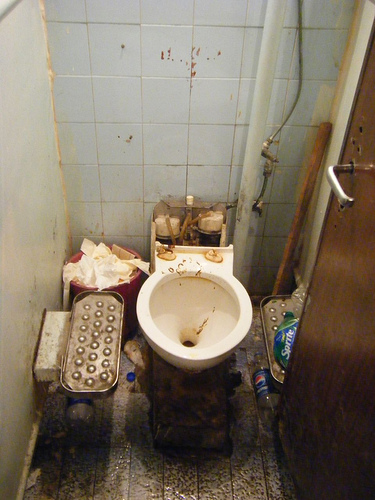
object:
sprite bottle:
[272, 310, 299, 371]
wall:
[42, 0, 358, 299]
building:
[0, 0, 374, 498]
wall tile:
[87, 23, 141, 79]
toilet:
[135, 195, 253, 450]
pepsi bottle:
[252, 350, 280, 422]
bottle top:
[123, 371, 135, 383]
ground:
[22, 301, 302, 498]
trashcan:
[63, 244, 142, 338]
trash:
[63, 237, 150, 310]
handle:
[325, 162, 354, 207]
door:
[274, 25, 374, 498]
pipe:
[230, 0, 288, 285]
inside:
[152, 207, 221, 245]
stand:
[60, 289, 125, 397]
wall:
[0, 0, 73, 498]